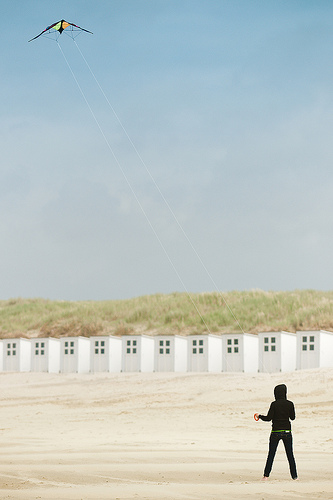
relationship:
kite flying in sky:
[28, 18, 95, 43] [1, 0, 331, 300]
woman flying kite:
[254, 383, 298, 480] [28, 18, 95, 43]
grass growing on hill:
[1, 290, 332, 338] [1, 289, 333, 334]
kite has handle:
[28, 18, 95, 43] [253, 412, 260, 422]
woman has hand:
[254, 383, 298, 480] [253, 412, 262, 419]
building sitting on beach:
[256, 330, 297, 375] [0, 366, 332, 500]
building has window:
[220, 332, 258, 372] [226, 338, 240, 354]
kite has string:
[28, 18, 95, 43] [56, 40, 261, 417]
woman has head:
[254, 383, 298, 480] [273, 383, 288, 401]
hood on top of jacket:
[273, 384, 287, 401] [258, 384, 296, 430]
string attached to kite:
[56, 40, 261, 417] [28, 18, 95, 43]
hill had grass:
[1, 289, 333, 334] [1, 290, 332, 338]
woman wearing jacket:
[254, 383, 298, 480] [258, 384, 296, 430]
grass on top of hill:
[1, 290, 332, 338] [1, 289, 333, 334]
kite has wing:
[28, 18, 95, 43] [70, 23, 95, 36]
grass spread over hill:
[1, 290, 332, 338] [1, 289, 333, 334]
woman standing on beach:
[254, 383, 298, 480] [0, 376, 332, 500]